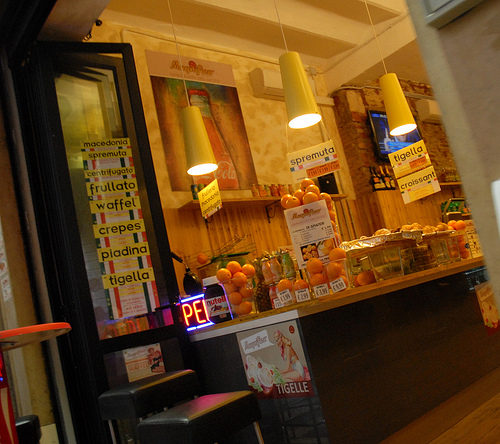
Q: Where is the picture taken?
A: A cafe.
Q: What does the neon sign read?
A: Open.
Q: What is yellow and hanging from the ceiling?
A: Lamps.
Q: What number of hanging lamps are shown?
A: 3.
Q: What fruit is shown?
A: Oranges.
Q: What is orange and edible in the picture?
A: Oranges.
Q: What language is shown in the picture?
A: Italian.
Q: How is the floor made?
A: Of wood.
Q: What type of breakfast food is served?
A: Waffles and crepes.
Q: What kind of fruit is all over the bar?
A: Oranges.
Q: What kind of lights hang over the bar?
A: Pendant lights.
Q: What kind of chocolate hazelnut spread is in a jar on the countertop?
A: Nutella.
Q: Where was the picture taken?
A: In a store.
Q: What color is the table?
A: Red.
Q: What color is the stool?
A: Gray.